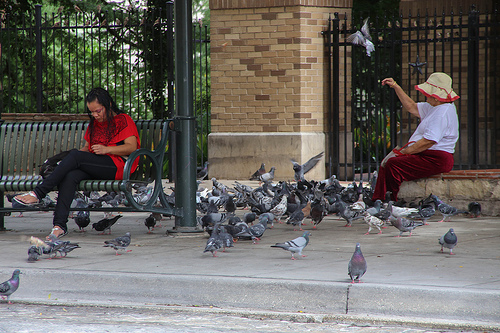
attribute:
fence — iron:
[40, 41, 222, 81]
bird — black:
[92, 199, 119, 236]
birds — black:
[4, 149, 499, 319]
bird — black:
[227, 217, 262, 243]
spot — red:
[244, 236, 261, 243]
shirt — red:
[79, 111, 144, 179]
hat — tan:
[411, 71, 459, 101]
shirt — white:
[410, 98, 460, 155]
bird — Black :
[1, 267, 24, 304]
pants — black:
[34, 142, 110, 222]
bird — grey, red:
[331, 237, 379, 287]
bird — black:
[343, 245, 369, 285]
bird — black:
[81, 216, 126, 234]